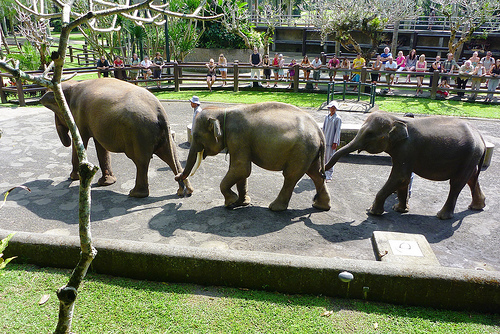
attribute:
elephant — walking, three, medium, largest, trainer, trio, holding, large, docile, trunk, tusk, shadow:
[29, 64, 401, 219]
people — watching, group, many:
[191, 23, 487, 95]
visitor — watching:
[234, 34, 446, 82]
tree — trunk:
[15, 168, 173, 296]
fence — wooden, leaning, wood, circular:
[225, 53, 415, 103]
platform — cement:
[201, 199, 390, 243]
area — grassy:
[131, 290, 315, 328]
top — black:
[253, 56, 263, 62]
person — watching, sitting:
[192, 45, 224, 89]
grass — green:
[101, 279, 195, 319]